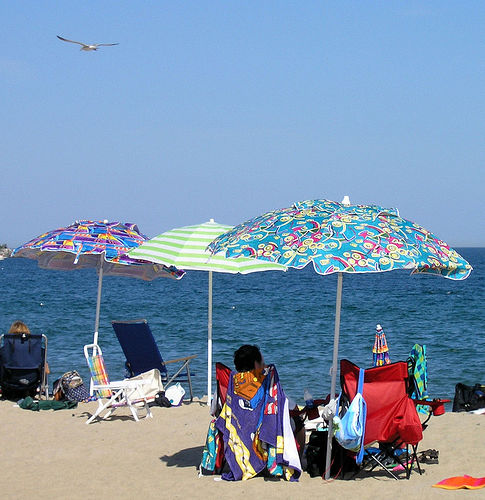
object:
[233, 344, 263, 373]
hair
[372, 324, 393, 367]
umbrella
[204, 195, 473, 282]
umbrella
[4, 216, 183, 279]
umbrella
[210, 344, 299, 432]
people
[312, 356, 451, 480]
chair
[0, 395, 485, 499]
beach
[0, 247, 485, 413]
water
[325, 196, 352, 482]
pole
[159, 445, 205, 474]
shadow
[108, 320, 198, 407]
chair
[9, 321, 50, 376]
lady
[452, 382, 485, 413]
bag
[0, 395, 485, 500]
sand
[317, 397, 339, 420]
bag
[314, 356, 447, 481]
seat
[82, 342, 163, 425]
chair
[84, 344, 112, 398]
back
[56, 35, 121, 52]
bird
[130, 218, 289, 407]
umbrella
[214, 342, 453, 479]
chair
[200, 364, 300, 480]
towel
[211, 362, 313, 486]
chair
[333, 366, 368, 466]
bag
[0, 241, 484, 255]
distance